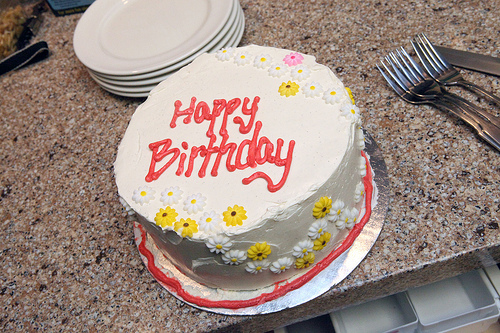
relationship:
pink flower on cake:
[274, 48, 310, 71] [104, 38, 378, 308]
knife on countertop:
[408, 32, 498, 89] [6, 112, 105, 310]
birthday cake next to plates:
[108, 47, 382, 297] [65, 52, 254, 102]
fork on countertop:
[371, 57, 498, 162] [2, 107, 497, 333]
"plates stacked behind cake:
[73, 2, 248, 100] [94, 52, 395, 311]